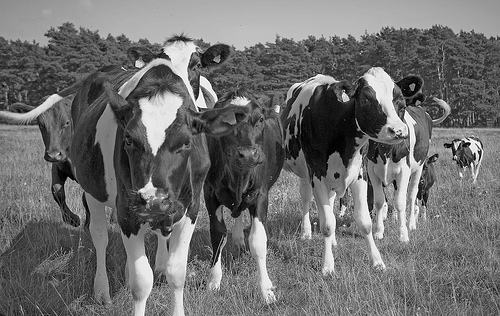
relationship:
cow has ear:
[185, 89, 284, 308] [183, 108, 210, 136]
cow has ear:
[124, 34, 232, 110] [203, 43, 231, 66]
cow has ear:
[272, 60, 426, 283] [326, 79, 358, 102]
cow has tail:
[1, 57, 211, 314] [0, 84, 82, 124]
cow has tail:
[370, 91, 455, 244] [424, 94, 452, 127]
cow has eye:
[62, 58, 251, 314] [178, 137, 191, 152]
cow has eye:
[62, 58, 251, 314] [123, 136, 137, 151]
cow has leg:
[198, 89, 284, 307] [248, 193, 280, 309]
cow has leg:
[272, 60, 426, 283] [312, 189, 348, 279]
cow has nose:
[62, 58, 248, 316] [130, 187, 171, 210]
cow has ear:
[62, 58, 251, 314] [192, 94, 261, 139]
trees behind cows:
[6, 16, 498, 123] [35, 34, 489, 314]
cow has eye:
[62, 58, 248, 316] [122, 133, 143, 154]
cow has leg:
[206, 87, 289, 308] [241, 178, 281, 312]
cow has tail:
[372, 96, 453, 254] [428, 85, 453, 130]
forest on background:
[1, 20, 499, 130] [6, 22, 496, 87]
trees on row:
[0, 20, 498, 123] [2, 18, 496, 130]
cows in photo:
[35, 34, 489, 314] [6, 2, 495, 314]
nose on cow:
[134, 180, 175, 215] [56, 45, 216, 271]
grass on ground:
[287, 266, 433, 291] [371, 280, 468, 304]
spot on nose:
[135, 164, 162, 214] [129, 170, 169, 212]